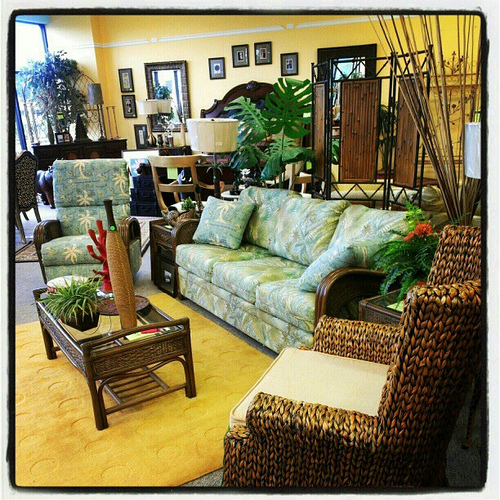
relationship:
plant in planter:
[38, 279, 98, 326] [61, 297, 101, 334]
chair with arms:
[33, 157, 140, 281] [33, 214, 152, 249]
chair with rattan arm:
[223, 225, 476, 490] [245, 389, 379, 464]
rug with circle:
[14, 291, 273, 486] [62, 402, 82, 421]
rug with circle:
[14, 291, 273, 486] [69, 410, 86, 443]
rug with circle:
[14, 291, 273, 486] [33, 370, 63, 396]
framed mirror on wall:
[150, 70, 184, 126] [100, 39, 247, 131]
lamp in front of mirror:
[137, 96, 165, 143] [146, 62, 190, 130]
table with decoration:
[33, 282, 208, 434] [110, 245, 140, 325]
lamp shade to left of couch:
[180, 114, 241, 156] [162, 181, 433, 364]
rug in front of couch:
[14, 291, 273, 486] [174, 182, 410, 355]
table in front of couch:
[33, 282, 208, 434] [174, 182, 410, 355]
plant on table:
[38, 270, 103, 326] [41, 320, 159, 381]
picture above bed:
[227, 42, 251, 69] [233, 82, 269, 97]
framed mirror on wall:
[150, 70, 184, 126] [103, 30, 223, 114]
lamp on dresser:
[84, 81, 107, 141] [34, 131, 129, 207]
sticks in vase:
[374, 13, 482, 220] [406, 227, 447, 289]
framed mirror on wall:
[144, 59, 193, 135] [177, 47, 207, 127]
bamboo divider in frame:
[306, 47, 443, 207] [315, 57, 427, 69]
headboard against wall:
[197, 79, 316, 122] [93, 18, 493, 188]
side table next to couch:
[148, 211, 201, 299] [174, 182, 410, 355]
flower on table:
[401, 218, 432, 248] [352, 266, 437, 337]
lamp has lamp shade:
[190, 113, 240, 198] [185, 117, 238, 153]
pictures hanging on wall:
[113, 67, 168, 108] [89, 17, 330, 158]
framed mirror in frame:
[150, 70, 184, 126] [143, 56, 192, 141]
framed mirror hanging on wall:
[150, 70, 184, 126] [66, 20, 326, 162]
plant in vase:
[374, 201, 469, 306] [408, 281, 426, 289]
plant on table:
[374, 231, 433, 291] [355, 277, 417, 327]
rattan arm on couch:
[301, 252, 408, 329] [174, 184, 448, 356]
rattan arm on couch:
[226, 386, 384, 497] [174, 184, 448, 356]